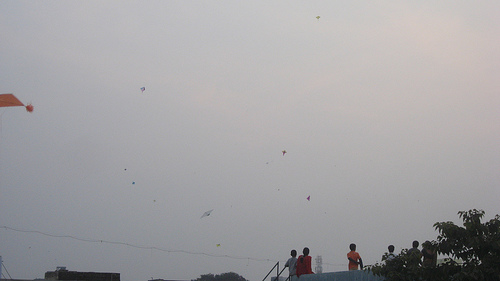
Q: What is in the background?
A: Powerline.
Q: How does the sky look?
A: It is grey.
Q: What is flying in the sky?
A: Kites are flying in the sky.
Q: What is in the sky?
A: A lot of kites.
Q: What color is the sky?
A: Grayish blue.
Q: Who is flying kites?
A: Kids.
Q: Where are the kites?
A: In the air.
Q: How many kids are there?
A: Six.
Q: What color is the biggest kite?
A: Orange.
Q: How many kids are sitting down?
A: Two.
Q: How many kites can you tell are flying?
A: Five.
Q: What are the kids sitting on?
A: A wall.